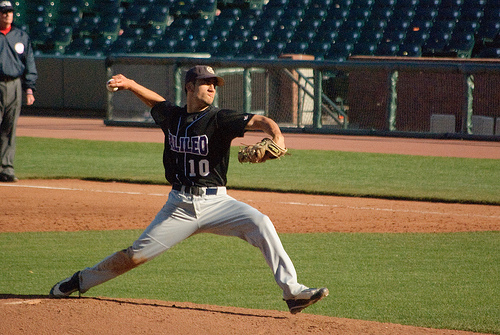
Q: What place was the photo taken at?
A: It was taken at the stadium.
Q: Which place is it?
A: It is a stadium.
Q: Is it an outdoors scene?
A: Yes, it is outdoors.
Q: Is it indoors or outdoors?
A: It is outdoors.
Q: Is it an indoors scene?
A: No, it is outdoors.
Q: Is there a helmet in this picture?
A: No, there are no helmets.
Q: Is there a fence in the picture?
A: Yes, there is a fence.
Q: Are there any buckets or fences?
A: Yes, there is a fence.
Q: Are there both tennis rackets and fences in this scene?
A: No, there is a fence but no rackets.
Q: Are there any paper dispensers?
A: No, there are no paper dispensers.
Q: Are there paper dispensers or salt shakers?
A: No, there are no paper dispensers or salt shakers.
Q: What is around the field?
A: The fence is around the field.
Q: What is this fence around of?
A: The fence is around the field.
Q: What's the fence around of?
A: The fence is around the field.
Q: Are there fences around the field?
A: Yes, there is a fence around the field.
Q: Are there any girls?
A: No, there are no girls.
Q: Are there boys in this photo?
A: No, there are no boys.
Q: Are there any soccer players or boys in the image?
A: No, there are no boys or soccer players.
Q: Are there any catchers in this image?
A: No, there are no catchers.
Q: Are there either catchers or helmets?
A: No, there are no catchers or helmets.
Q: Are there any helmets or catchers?
A: No, there are no catchers or helmets.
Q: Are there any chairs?
A: Yes, there is a chair.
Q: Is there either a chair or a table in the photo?
A: Yes, there is a chair.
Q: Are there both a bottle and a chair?
A: No, there is a chair but no bottles.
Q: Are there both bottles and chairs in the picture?
A: No, there is a chair but no bottles.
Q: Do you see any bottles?
A: No, there are no bottles.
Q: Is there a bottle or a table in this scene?
A: No, there are no bottles or tables.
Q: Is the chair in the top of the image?
A: Yes, the chair is in the top of the image.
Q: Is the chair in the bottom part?
A: No, the chair is in the top of the image.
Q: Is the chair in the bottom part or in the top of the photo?
A: The chair is in the top of the image.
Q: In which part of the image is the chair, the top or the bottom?
A: The chair is in the top of the image.